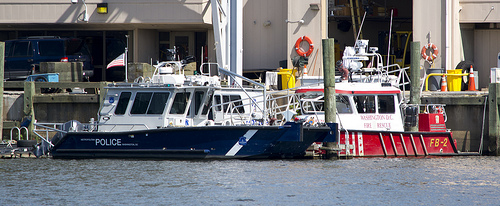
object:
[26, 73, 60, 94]
car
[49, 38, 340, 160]
blue boat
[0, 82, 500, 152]
boardwalk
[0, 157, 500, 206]
ocean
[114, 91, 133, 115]
window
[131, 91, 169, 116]
window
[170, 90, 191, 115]
window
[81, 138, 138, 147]
writing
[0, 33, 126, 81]
car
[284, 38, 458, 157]
boat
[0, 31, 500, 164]
dock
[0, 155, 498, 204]
water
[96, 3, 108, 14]
light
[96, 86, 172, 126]
back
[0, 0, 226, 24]
wall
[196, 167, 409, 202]
section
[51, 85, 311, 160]
side